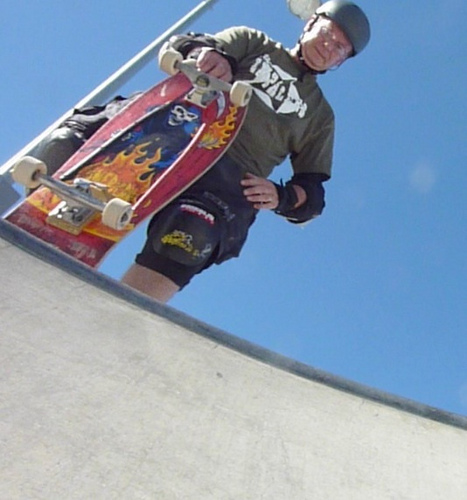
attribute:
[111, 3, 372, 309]
man — old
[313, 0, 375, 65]
helmet — grey, green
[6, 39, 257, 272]
skateboard — red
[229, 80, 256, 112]
wheel — white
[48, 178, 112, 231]
trucks — metal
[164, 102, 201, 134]
face — white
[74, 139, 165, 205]
flame — orange, red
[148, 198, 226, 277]
knee pad — black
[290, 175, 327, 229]
elbow pad — black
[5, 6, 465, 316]
sky — clear, blue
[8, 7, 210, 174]
pole — grey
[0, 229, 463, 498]
ramp — white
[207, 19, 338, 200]
shirt — grey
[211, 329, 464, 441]
lip — blue